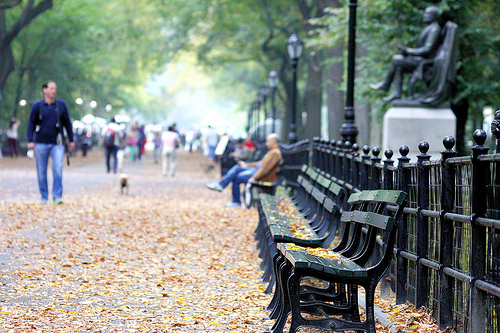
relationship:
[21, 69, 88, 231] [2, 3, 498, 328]
man walks in park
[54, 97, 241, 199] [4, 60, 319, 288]
people walk in park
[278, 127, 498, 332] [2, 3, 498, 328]
fence in park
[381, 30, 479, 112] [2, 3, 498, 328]
statue in park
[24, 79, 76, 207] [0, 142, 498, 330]
man walking on sidewalk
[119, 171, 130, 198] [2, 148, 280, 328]
dog standing on walkway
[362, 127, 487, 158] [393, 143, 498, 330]
balls on top of fence posts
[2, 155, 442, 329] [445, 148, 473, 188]
leaves on ground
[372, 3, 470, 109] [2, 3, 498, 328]
statue in park